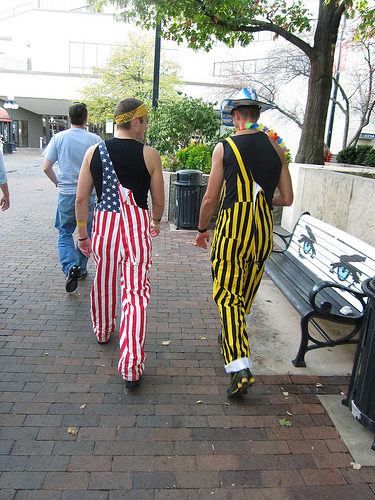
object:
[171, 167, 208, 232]
trashcan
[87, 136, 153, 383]
overalls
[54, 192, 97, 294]
jeans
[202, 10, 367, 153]
tree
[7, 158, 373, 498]
sidewalk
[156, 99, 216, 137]
green leaves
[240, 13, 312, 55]
tree branch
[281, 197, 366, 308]
bench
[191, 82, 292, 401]
man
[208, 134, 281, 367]
clothes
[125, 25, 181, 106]
lightpole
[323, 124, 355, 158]
ground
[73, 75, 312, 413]
men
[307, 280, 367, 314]
armrest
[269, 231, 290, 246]
armrest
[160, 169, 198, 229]
garbage can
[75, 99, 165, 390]
body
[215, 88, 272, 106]
hat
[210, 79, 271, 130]
head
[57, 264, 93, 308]
shoe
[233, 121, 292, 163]
lei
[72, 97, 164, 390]
man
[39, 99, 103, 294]
man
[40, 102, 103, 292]
person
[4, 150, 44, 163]
street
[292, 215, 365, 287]
eyes